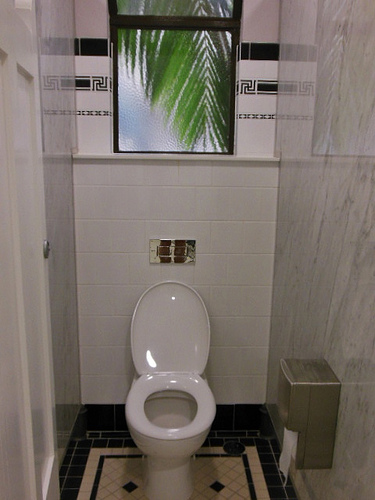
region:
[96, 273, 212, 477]
the toilet is white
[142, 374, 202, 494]
the toilet is white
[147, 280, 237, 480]
the toilet is white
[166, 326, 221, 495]
the toilet is white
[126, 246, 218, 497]
the commode is white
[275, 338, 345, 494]
the toilet paper holder is chrome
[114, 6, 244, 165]
a palm tree is out side the window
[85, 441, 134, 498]
the floor is tiled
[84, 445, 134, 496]
the tile is black & white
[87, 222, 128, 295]
the walls are tiled in white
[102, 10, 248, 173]
the window is trimmed in black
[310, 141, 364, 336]
the wall appears to be marble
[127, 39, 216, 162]
the window glass is frosted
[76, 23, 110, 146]
the wall is tiled in black & white as well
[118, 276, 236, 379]
The toilet seat is raised.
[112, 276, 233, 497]
The toilet is white.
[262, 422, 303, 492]
The toilet paper hangs on the wall.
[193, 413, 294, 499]
The floor is tiled.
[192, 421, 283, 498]
The floor is black and beige.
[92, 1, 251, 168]
A window is on the wall.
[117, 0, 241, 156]
A palm tree is seen through the window.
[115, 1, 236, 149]
The palm tree is green.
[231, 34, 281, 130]
A pattern is on the wall.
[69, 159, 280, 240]
The wall is white.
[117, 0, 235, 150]
a green palm leaf outside a window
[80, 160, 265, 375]
a white tile wall behind a toilet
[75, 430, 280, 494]
a black and white tile bathroom floor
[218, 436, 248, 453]
a drain in a bathroom floor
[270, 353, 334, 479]
a toilet paper holder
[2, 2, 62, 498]
a white door on a bathroomstall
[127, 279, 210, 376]
a lid in the up position on a toilet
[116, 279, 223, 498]
a white toilet in a bthroom stall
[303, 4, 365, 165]
the reflection of a palm leaf on a wall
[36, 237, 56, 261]
a lock on a bathroom stall door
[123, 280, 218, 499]
a white toilet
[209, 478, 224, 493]
a black tile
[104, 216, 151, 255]
a white wall tile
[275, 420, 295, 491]
white toilet paper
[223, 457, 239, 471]
white or beige floor tile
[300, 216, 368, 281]
a grey and white marble wall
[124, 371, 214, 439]
a white toilet seat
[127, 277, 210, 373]
a white toilet lid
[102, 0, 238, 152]
a bathroom window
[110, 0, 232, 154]
a green palm leaf